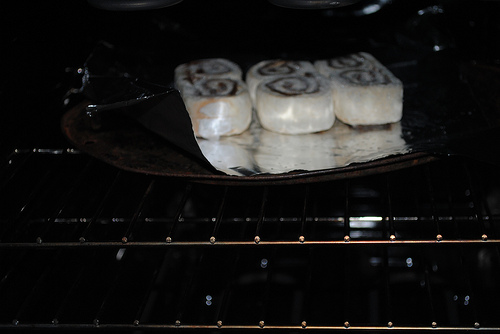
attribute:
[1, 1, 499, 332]
oven — dark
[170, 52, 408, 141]
cinnamon rolls — white, raw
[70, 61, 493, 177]
foil — aluminum, silver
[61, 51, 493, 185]
pan — curled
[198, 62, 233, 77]
design — swirled, brown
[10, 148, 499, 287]
rack — metal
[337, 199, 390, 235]
spot — shiny